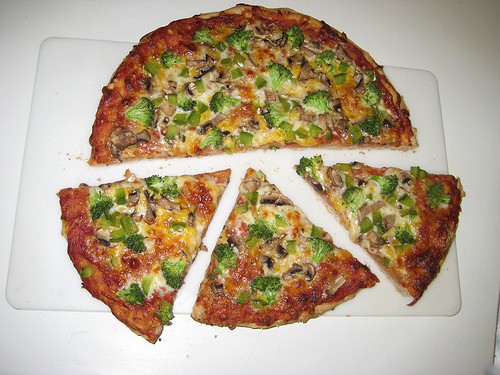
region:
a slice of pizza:
[271, 151, 466, 312]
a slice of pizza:
[61, 167, 230, 347]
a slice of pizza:
[196, 164, 368, 344]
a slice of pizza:
[63, 1, 425, 154]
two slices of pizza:
[185, 152, 463, 324]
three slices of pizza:
[39, 147, 463, 347]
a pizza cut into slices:
[55, 2, 471, 357]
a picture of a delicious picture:
[37, 4, 477, 344]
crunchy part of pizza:
[58, 186, 99, 258]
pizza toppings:
[189, 42, 321, 140]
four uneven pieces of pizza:
[52, 6, 464, 348]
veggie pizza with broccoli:
[251, 272, 284, 304]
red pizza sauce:
[191, 270, 377, 322]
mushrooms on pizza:
[263, 235, 315, 281]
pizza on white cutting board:
[2, 0, 471, 349]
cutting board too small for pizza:
[4, 35, 462, 315]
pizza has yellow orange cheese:
[143, 207, 194, 262]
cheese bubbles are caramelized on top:
[227, 64, 257, 131]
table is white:
[3, 0, 495, 373]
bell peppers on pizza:
[104, 210, 141, 245]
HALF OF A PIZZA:
[81, 0, 431, 160]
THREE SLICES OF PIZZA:
[46, 158, 471, 351]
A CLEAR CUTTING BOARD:
[11, 36, 482, 335]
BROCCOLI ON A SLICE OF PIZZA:
[119, 246, 191, 340]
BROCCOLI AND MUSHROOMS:
[101, 61, 207, 153]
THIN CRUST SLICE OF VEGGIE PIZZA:
[182, 167, 390, 342]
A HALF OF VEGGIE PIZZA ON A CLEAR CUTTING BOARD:
[87, 1, 438, 163]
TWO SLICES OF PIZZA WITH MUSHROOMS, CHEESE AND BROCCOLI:
[195, 153, 465, 336]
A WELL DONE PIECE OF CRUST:
[399, 171, 471, 306]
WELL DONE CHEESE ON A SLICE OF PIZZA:
[172, 163, 220, 259]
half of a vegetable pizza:
[72, 7, 459, 162]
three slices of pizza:
[43, 148, 475, 345]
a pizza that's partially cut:
[57, 10, 462, 336]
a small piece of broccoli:
[161, 251, 193, 291]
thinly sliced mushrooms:
[123, 182, 188, 220]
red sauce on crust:
[58, 185, 111, 304]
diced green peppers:
[105, 185, 137, 240]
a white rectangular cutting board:
[6, 1, 485, 353]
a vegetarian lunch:
[20, 9, 468, 351]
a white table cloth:
[6, 2, 485, 357]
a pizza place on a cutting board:
[46, 30, 463, 344]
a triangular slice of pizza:
[320, 157, 471, 276]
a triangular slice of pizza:
[200, 172, 348, 340]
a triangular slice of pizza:
[61, 172, 238, 349]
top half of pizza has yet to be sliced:
[85, 4, 435, 155]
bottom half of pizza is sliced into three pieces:
[62, 170, 460, 325]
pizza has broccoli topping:
[297, 146, 476, 336]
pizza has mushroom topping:
[218, 179, 371, 364]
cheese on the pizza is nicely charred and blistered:
[80, 23, 428, 147]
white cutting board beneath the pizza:
[2, 37, 66, 327]